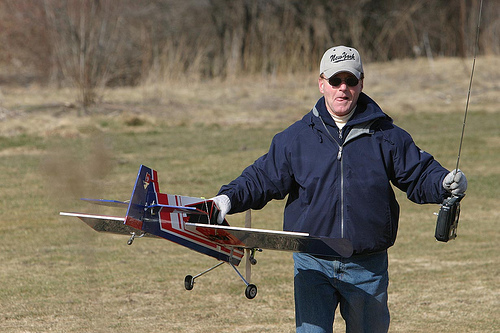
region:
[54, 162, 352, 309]
The remote controlled airplane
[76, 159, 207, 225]
The tail of the airplane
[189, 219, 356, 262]
The right wing of the airplane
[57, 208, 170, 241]
The left wing of the plane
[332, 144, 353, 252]
The zipper of the jacket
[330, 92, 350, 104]
The tongue sticking out of the mouth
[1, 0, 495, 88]
The brown plants at the field's edge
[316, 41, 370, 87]
The hat the man is wearing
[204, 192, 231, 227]
The hand holding the plane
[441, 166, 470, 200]
The hand holding the remote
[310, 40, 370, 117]
the head of a man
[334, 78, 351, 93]
the nose of a man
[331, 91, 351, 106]
the mouth of a man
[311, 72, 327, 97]
the ear of a man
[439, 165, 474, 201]
the hand of a man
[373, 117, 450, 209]
the arm of a man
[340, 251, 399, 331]
the leg of a man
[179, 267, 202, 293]
a wheel on the plane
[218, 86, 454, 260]
a navy blue jacket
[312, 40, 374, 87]
a gray baseball cap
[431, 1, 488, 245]
The remote for the airplane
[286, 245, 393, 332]
The jeans of the man shown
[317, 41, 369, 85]
The hat of the man iwth the plane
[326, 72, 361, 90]
The sunglasses on the man's face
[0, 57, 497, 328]
The grass field the man is standing in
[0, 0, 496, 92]
The large brown bushes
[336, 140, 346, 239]
The zipper on the front of the jacket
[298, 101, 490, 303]
a man in blue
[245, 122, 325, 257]
a man in blue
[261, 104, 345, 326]
a man in blue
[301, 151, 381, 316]
a man in blue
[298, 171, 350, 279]
a man in blue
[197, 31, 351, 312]
a man in blue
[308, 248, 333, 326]
a man in blue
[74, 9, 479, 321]
man carrying toy plane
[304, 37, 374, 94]
baseball cap on man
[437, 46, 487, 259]
remote control in hand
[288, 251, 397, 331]
blue jeans on man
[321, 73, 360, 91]
dark sunglasses on man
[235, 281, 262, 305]
side landing wheel on plane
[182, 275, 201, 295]
side landing wheel on plane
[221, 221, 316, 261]
side wing of plane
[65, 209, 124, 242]
side landing wheel on plane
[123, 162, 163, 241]
tail wing of plane